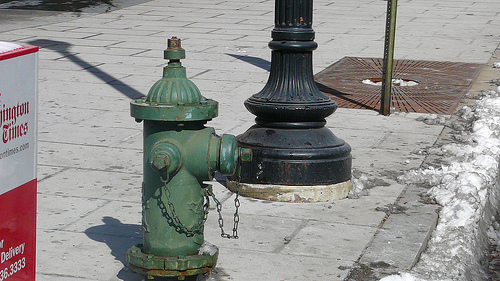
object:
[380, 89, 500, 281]
snow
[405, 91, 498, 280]
curb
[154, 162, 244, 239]
chain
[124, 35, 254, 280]
hydrant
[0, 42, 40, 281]
paper machine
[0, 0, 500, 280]
sidewalk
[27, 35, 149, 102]
shadow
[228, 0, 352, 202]
pole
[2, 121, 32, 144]
time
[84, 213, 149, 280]
shadow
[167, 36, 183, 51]
nozzle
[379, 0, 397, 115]
pole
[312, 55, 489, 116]
cover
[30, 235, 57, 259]
phone number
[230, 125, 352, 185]
bottom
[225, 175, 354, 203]
concrete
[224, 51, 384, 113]
shadow